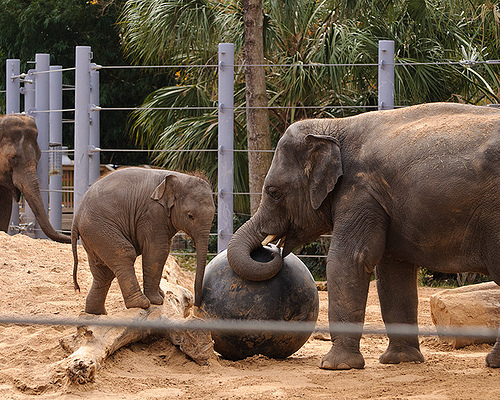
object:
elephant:
[226, 101, 499, 369]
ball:
[202, 245, 318, 360]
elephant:
[0, 113, 72, 243]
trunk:
[243, 0, 273, 222]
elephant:
[72, 167, 215, 314]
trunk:
[227, 208, 282, 282]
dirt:
[0, 231, 499, 398]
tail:
[71, 215, 82, 293]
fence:
[1, 40, 499, 252]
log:
[24, 253, 220, 387]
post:
[217, 42, 233, 253]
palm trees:
[101, 1, 498, 287]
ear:
[150, 174, 175, 216]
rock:
[428, 280, 498, 348]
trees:
[0, 0, 203, 161]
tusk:
[259, 232, 275, 247]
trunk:
[13, 164, 77, 243]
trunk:
[192, 221, 212, 309]